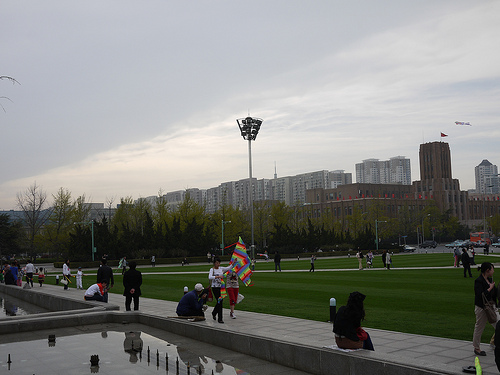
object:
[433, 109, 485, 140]
flag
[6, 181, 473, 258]
trees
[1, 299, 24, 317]
water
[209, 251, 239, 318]
woman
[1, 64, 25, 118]
branches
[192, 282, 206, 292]
hat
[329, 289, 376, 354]
woman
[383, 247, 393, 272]
woman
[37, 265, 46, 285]
woman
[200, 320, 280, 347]
ledge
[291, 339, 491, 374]
ledge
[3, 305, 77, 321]
ledge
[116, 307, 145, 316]
ledge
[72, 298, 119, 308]
ledge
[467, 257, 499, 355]
woman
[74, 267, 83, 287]
child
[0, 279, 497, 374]
sidewalk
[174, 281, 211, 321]
man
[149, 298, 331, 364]
cement ledge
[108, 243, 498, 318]
green-grassy field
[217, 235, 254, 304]
kite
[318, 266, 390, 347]
person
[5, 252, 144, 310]
people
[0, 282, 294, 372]
pond